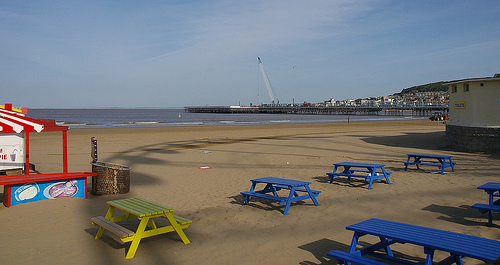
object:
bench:
[89, 197, 193, 260]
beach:
[0, 119, 499, 264]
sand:
[141, 124, 319, 171]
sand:
[212, 211, 299, 261]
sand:
[8, 211, 73, 259]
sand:
[304, 127, 373, 155]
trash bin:
[90, 137, 132, 196]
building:
[440, 74, 500, 151]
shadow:
[104, 136, 252, 180]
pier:
[185, 106, 451, 117]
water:
[44, 106, 74, 121]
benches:
[90, 216, 135, 243]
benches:
[161, 208, 193, 226]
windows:
[463, 83, 471, 92]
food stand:
[0, 103, 95, 207]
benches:
[325, 218, 500, 265]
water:
[151, 108, 177, 118]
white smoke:
[259, 63, 279, 100]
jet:
[257, 56, 263, 64]